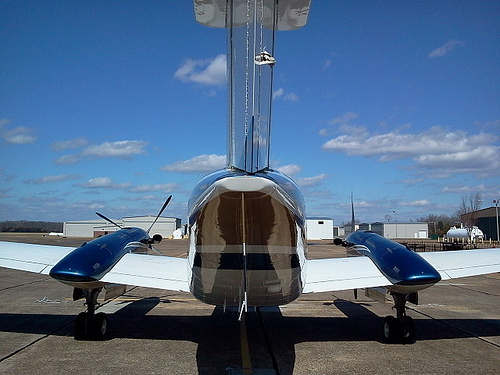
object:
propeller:
[145, 195, 173, 236]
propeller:
[94, 210, 124, 230]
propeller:
[353, 285, 358, 298]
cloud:
[46, 136, 90, 152]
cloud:
[167, 52, 230, 100]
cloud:
[156, 154, 229, 174]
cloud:
[42, 137, 148, 171]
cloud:
[314, 109, 499, 198]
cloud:
[419, 35, 458, 59]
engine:
[343, 229, 443, 285]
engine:
[49, 226, 151, 291]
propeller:
[148, 244, 163, 254]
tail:
[193, 2, 312, 173]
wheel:
[90, 311, 110, 341]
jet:
[0, 1, 499, 345]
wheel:
[74, 311, 90, 341]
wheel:
[379, 316, 400, 344]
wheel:
[401, 315, 418, 344]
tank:
[445, 225, 484, 240]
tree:
[450, 192, 485, 242]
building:
[120, 216, 182, 240]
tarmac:
[0, 232, 499, 374]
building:
[372, 221, 430, 242]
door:
[419, 229, 429, 239]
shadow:
[1, 296, 499, 374]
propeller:
[347, 190, 355, 232]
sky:
[1, 0, 499, 226]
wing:
[0, 240, 190, 293]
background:
[1, 0, 499, 374]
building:
[302, 216, 334, 241]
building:
[460, 207, 500, 246]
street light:
[490, 198, 498, 205]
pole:
[496, 210, 500, 241]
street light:
[497, 200, 500, 203]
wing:
[303, 248, 499, 294]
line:
[239, 294, 254, 374]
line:
[62, 296, 203, 303]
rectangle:
[319, 221, 325, 225]